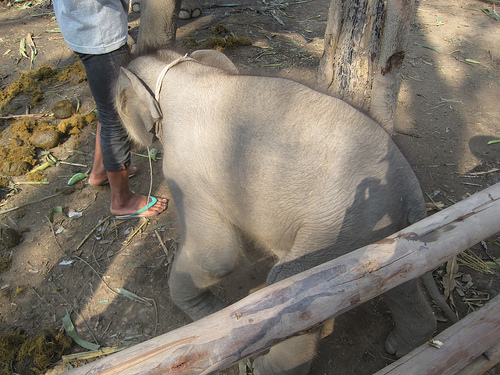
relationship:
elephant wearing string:
[114, 48, 463, 358] [153, 53, 196, 140]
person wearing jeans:
[50, 0, 169, 216] [74, 44, 132, 170]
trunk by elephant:
[318, 0, 420, 137] [114, 48, 463, 358]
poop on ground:
[1, 59, 99, 197] [1, 0, 499, 374]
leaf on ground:
[466, 57, 492, 72] [1, 0, 499, 374]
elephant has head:
[114, 48, 463, 358] [117, 48, 238, 150]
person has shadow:
[50, 0, 169, 216] [21, 213, 146, 351]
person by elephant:
[50, 0, 169, 216] [114, 48, 463, 358]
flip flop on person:
[117, 196, 158, 218] [50, 0, 169, 216]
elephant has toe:
[114, 48, 463, 358] [385, 335, 407, 360]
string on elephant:
[153, 56, 197, 140] [114, 48, 463, 358]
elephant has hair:
[114, 48, 463, 358] [112, 38, 191, 60]